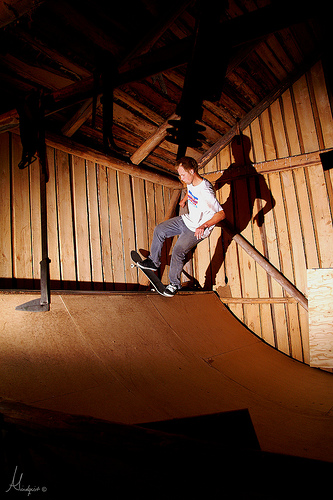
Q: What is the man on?
A: Skateboard.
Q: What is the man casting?
A: Shadow.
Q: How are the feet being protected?
A: Shoes.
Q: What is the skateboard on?
A: Ramp.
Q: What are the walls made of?
A: Wood.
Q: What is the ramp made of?
A: Wood.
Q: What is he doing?
A: Skating.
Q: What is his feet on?
A: Board.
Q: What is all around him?
A: Wood.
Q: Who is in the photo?
A: Boy.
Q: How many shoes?
A: 2.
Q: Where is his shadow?
A: Behind him.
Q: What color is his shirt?
A: White.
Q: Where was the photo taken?
A: At a indoor halfpipe.